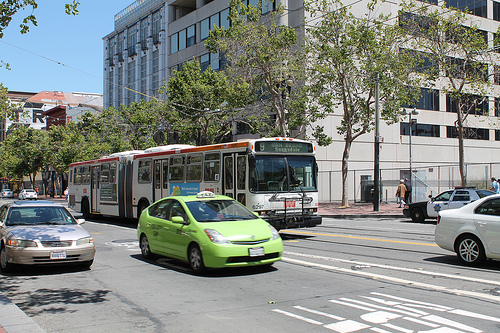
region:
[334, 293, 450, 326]
White lines on tarmac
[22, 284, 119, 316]
Small scattered tree shadow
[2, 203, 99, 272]
Small grey saloon car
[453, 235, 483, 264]
White circular vehicle rim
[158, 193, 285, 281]
Luminous green small taxi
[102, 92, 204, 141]
Green trees on sidewalk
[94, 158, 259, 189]
Long white and red bus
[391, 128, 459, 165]
A big white building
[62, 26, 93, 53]
Clear cloudless blue sky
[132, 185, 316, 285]
the taxi is green in color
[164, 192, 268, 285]
the taxi is moving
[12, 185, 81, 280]
the car is silvery in color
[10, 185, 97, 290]
the car is parked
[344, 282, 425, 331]
the road has white marks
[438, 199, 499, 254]
car is white in color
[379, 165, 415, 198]
two people walking towards the building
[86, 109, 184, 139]
trees are green in color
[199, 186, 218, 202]
Taxi sign on top of car.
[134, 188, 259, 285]
Light green car in road.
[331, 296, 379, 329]
White lines marking road.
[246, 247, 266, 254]
White license plate on car.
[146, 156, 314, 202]
Bus driving on road.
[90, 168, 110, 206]
Door on side of bus.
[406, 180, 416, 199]
Person wearing black coat.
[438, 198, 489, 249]
White car driving on road.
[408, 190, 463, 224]
Police car on side of road.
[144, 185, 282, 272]
the taxi is green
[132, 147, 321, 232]
the bus is red and white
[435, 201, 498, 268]
the car is white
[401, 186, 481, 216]
the police car is packed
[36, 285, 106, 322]
shadow is on the ground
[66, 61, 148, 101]
electrical wire are in the air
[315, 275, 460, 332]
letters are white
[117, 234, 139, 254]
manhole cover is on the ground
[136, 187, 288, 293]
This is a car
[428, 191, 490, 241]
This is a car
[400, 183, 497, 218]
This is a car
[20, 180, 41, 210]
This is a car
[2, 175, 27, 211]
This is a car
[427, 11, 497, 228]
This is a tree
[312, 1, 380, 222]
This is a tree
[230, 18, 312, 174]
This is a tree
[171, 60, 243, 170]
This is a tree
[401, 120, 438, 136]
glass window on the building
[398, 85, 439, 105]
glass window on the building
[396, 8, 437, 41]
glass window on the building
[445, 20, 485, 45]
glass window on the building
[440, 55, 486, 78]
glass window on the building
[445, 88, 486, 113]
glass window on the building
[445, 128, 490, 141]
glass window on the building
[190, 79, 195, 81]
A green leaf on a plant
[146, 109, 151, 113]
A green leaf on a plant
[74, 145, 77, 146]
A green leaf on a plant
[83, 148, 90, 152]
A green leaf on a plant